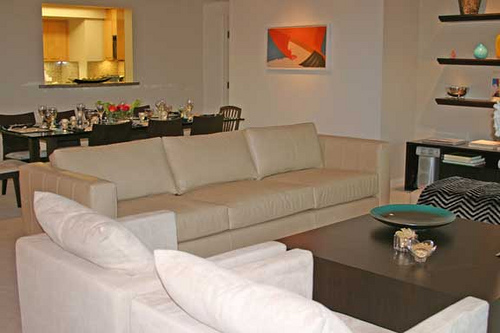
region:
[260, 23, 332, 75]
a picture of a women wearing a hat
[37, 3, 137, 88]
a window into the kitchen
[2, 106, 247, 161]
the dining room table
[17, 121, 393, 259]
a white leather couch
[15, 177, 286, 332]
a white chair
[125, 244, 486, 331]
a white chair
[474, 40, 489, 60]
a light blue vase on a shelf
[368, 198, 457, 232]
a turquoise bowl on the table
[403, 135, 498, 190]
a desk against the wall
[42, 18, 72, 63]
kitchen cabinets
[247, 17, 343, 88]
a painting on the wall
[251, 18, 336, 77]
a painting on the wall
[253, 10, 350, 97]
a painting on the wall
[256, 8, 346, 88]
a painting on the wall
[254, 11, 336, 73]
a painting on the wall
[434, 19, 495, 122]
decorations on the shelf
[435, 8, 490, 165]
decorations on the shelf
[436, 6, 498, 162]
decorations on the shelf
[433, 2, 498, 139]
decorations on the shelf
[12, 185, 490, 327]
White sofa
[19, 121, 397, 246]
Long tan sofa with three cushions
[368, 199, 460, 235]
Green and brown glass bowl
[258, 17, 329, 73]
Painting hanging on the wall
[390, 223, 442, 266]
Two small votive candles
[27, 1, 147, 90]
Window in the wall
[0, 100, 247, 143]
Dining table covered with cutlery and flowrs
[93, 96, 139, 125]
Red flower centerpiece on the table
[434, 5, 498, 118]
Row of brown shelves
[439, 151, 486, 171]
Stack of magazines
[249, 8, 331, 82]
image on the wall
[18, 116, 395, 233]
sofa in the room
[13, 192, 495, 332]
sofa in the room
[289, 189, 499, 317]
table in the room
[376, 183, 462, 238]
platter in center of table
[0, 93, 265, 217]
table and set of chairs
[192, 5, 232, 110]
doorway to the room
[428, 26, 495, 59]
items on a shelf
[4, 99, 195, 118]
dishware on the table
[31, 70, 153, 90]
bar area of kitchen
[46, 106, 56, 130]
glass on dining table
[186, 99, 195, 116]
glass on dining table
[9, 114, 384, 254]
a light brown sofa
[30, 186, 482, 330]
a pair of chairs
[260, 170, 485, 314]
a brown coffee table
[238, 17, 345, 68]
picture on the wall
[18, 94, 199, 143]
a long dining table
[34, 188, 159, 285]
pillow in the chair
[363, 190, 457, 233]
platter in the table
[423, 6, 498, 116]
a set of shelves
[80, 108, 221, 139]
a row of chairs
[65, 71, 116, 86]
platter on the counter